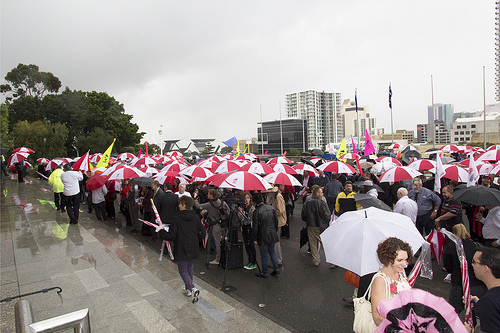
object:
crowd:
[0, 143, 500, 266]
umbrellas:
[139, 152, 341, 188]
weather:
[0, 0, 500, 166]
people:
[89, 143, 497, 278]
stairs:
[12, 297, 93, 333]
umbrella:
[316, 206, 429, 277]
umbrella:
[372, 288, 473, 333]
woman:
[350, 236, 469, 332]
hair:
[378, 238, 407, 263]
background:
[0, 0, 500, 333]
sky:
[0, 0, 500, 146]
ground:
[0, 199, 341, 333]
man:
[59, 165, 86, 227]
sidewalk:
[0, 173, 134, 333]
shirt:
[59, 171, 84, 197]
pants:
[62, 193, 80, 224]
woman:
[134, 195, 204, 304]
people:
[44, 164, 84, 225]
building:
[255, 119, 310, 158]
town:
[248, 65, 500, 150]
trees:
[0, 62, 167, 157]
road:
[1, 162, 89, 285]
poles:
[385, 85, 394, 144]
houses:
[161, 139, 220, 158]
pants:
[173, 253, 199, 295]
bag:
[349, 298, 372, 333]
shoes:
[241, 262, 257, 271]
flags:
[384, 82, 394, 109]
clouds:
[0, 0, 500, 106]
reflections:
[26, 190, 79, 258]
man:
[465, 249, 498, 333]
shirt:
[467, 286, 500, 332]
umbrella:
[457, 255, 475, 324]